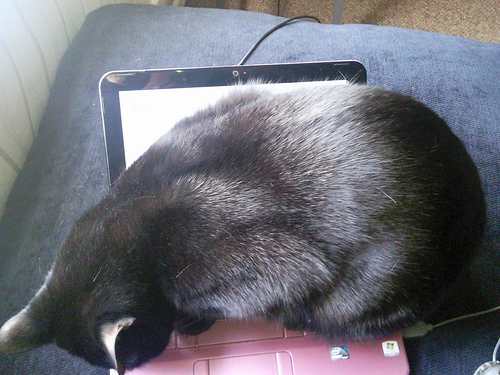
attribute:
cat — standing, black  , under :
[17, 78, 478, 361]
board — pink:
[124, 302, 407, 372]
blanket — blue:
[0, 16, 483, 290]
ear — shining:
[93, 303, 141, 372]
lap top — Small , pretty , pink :
[92, 43, 415, 369]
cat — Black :
[7, 64, 485, 370]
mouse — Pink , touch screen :
[198, 348, 292, 373]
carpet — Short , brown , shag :
[182, 2, 498, 42]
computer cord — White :
[402, 297, 498, 337]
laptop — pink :
[96, 43, 409, 369]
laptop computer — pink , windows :
[87, 45, 439, 369]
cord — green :
[400, 293, 497, 336]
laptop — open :
[71, 36, 451, 365]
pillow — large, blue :
[3, 14, 497, 373]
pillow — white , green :
[2, 7, 82, 238]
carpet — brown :
[173, 0, 497, 52]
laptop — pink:
[285, 343, 329, 364]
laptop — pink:
[297, 347, 326, 366]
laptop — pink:
[296, 352, 326, 372]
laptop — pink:
[297, 327, 320, 366]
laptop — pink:
[303, 341, 329, 372]